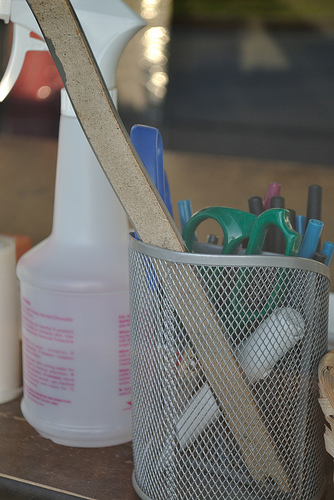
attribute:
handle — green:
[199, 205, 296, 278]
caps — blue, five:
[258, 174, 330, 203]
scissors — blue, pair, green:
[133, 127, 177, 188]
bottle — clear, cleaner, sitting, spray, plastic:
[51, 155, 145, 446]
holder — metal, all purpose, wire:
[133, 274, 332, 467]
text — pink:
[32, 292, 83, 404]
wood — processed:
[64, 33, 155, 173]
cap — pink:
[253, 184, 290, 214]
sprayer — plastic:
[10, 44, 127, 422]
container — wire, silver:
[164, 247, 301, 449]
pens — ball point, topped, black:
[184, 176, 326, 338]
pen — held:
[289, 198, 332, 302]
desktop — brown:
[12, 419, 76, 487]